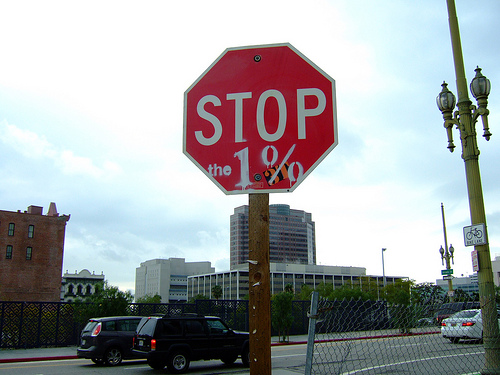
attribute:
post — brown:
[248, 190, 271, 372]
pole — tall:
[435, 3, 487, 369]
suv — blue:
[65, 314, 132, 363]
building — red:
[0, 203, 72, 346]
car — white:
[441, 308, 484, 342]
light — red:
[457, 317, 481, 331]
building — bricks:
[68, 182, 456, 354]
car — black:
[133, 312, 266, 367]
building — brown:
[2, 194, 107, 325]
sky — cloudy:
[11, 6, 496, 293]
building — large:
[228, 202, 317, 269]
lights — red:
[440, 320, 472, 327]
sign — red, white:
[180, 40, 338, 199]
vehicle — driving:
[134, 319, 261, 366]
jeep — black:
[138, 305, 260, 372]